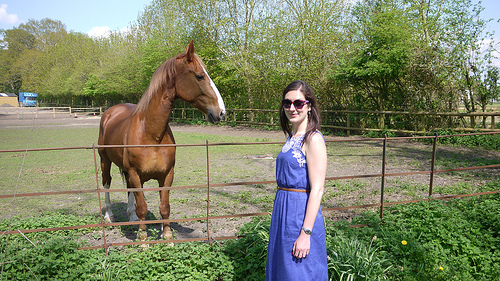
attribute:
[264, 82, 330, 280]
woman — standing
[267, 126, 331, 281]
dress — sleeveless, purple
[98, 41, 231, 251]
horse — standing, brown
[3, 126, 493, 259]
fence — metal, rusty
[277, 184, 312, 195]
belt — brown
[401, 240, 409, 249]
flower — yellow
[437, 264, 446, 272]
flower — yellow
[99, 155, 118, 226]
leg — white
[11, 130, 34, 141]
grass — green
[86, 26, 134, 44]
cloud — white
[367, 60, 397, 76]
leaves — green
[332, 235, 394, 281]
bush — green